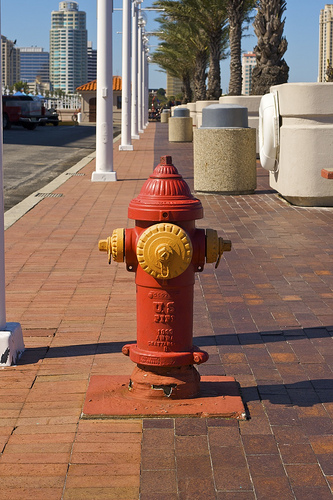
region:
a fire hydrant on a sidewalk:
[102, 164, 232, 391]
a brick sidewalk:
[54, 132, 304, 488]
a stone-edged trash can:
[189, 99, 271, 224]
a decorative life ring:
[253, 93, 291, 184]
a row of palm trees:
[171, 11, 294, 92]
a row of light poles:
[90, 17, 161, 173]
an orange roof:
[67, 73, 152, 103]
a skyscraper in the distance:
[49, 18, 92, 115]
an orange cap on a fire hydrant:
[128, 214, 201, 310]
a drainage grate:
[32, 186, 73, 205]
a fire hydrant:
[94, 149, 232, 395]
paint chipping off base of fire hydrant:
[87, 369, 249, 422]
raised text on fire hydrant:
[139, 287, 182, 353]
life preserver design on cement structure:
[252, 79, 317, 205]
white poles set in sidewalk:
[92, 0, 157, 187]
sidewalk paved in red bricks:
[11, 422, 299, 488]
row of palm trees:
[150, 0, 263, 105]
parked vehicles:
[0, 91, 63, 132]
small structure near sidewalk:
[76, 71, 161, 141]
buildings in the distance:
[1, 0, 100, 116]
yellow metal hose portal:
[137, 225, 202, 280]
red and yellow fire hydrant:
[94, 170, 261, 404]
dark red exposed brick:
[232, 247, 288, 474]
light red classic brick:
[51, 216, 122, 477]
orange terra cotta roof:
[71, 65, 140, 95]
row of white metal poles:
[118, 17, 142, 183]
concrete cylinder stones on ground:
[171, 111, 270, 198]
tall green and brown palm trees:
[139, 14, 295, 56]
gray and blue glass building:
[30, 5, 111, 128]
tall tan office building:
[316, 6, 331, 91]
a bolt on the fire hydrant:
[158, 150, 177, 166]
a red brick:
[67, 439, 142, 457]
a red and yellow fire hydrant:
[93, 150, 241, 396]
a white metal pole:
[90, 0, 116, 184]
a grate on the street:
[33, 187, 67, 202]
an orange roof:
[74, 72, 131, 93]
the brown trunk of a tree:
[223, 12, 249, 95]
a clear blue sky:
[1, 0, 332, 88]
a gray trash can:
[194, 100, 249, 129]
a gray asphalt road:
[4, 116, 128, 213]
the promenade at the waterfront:
[0, 97, 332, 498]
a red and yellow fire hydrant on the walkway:
[80, 156, 245, 419]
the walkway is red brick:
[13, 117, 330, 492]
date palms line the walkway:
[152, 1, 289, 164]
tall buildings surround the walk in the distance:
[2, 4, 332, 148]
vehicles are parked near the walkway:
[3, 89, 165, 142]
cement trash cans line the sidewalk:
[159, 104, 259, 195]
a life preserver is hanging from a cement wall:
[255, 84, 320, 211]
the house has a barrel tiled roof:
[75, 74, 130, 130]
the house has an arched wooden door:
[77, 76, 98, 123]